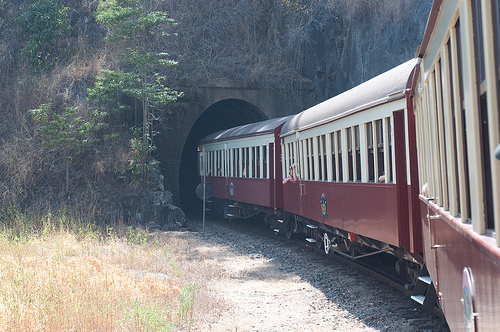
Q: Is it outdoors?
A: Yes, it is outdoors.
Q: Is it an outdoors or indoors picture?
A: It is outdoors.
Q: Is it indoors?
A: No, it is outdoors.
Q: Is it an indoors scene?
A: No, it is outdoors.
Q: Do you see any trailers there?
A: No, there are no trailers.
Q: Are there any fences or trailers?
A: No, there are no trailers or fences.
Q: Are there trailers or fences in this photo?
A: No, there are no trailers or fences.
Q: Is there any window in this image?
A: Yes, there is a window.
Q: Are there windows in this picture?
A: Yes, there is a window.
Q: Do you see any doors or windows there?
A: Yes, there is a window.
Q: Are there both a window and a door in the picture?
A: No, there is a window but no doors.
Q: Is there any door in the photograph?
A: No, there are no doors.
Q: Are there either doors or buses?
A: No, there are no doors or buses.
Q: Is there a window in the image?
A: Yes, there is a window.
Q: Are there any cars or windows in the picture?
A: Yes, there is a window.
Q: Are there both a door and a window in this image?
A: No, there is a window but no doors.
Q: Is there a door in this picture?
A: No, there are no doors.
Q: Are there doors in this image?
A: No, there are no doors.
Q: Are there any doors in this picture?
A: No, there are no doors.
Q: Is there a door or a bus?
A: No, there are no doors or buses.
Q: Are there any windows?
A: Yes, there is a window.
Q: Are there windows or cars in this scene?
A: Yes, there is a window.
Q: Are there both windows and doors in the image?
A: No, there is a window but no doors.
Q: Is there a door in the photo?
A: No, there are no doors.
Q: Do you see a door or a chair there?
A: No, there are no doors or chairs.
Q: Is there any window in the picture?
A: Yes, there are windows.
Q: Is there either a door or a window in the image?
A: Yes, there are windows.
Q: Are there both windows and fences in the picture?
A: No, there are windows but no fences.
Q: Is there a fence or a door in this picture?
A: No, there are no doors or fences.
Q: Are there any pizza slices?
A: No, there are no pizza slices.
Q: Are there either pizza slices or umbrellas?
A: No, there are no pizza slices or umbrellas.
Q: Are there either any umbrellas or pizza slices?
A: No, there are no pizza slices or umbrellas.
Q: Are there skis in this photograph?
A: No, there are no skis.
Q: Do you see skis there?
A: No, there are no skis.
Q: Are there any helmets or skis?
A: No, there are no skis or helmets.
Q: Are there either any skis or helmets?
A: No, there are no skis or helmets.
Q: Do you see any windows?
A: Yes, there is a window.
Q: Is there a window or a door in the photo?
A: Yes, there is a window.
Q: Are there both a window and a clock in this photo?
A: No, there is a window but no clocks.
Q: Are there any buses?
A: No, there are no buses.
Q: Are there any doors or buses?
A: No, there are no buses or doors.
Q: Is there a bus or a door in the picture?
A: No, there are no buses or doors.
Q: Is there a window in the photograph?
A: Yes, there is a window.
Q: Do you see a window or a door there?
A: Yes, there is a window.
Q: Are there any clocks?
A: No, there are no clocks.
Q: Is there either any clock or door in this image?
A: No, there are no clocks or doors.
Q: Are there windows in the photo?
A: Yes, there are windows.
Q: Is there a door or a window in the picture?
A: Yes, there are windows.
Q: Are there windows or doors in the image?
A: Yes, there are windows.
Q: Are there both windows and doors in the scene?
A: No, there are windows but no doors.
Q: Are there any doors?
A: No, there are no doors.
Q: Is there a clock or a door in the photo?
A: No, there are no doors or clocks.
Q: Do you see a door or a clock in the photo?
A: No, there are no doors or clocks.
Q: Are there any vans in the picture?
A: No, there are no vans.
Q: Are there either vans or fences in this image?
A: No, there are no vans or fences.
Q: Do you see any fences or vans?
A: No, there are no vans or fences.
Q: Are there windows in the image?
A: Yes, there are windows.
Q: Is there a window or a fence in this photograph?
A: Yes, there are windows.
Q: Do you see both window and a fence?
A: No, there are windows but no fences.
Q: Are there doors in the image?
A: No, there are no doors.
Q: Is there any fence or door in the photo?
A: No, there are no doors or fences.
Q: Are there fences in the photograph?
A: No, there are no fences.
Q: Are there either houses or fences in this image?
A: No, there are no fences or houses.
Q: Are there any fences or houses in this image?
A: No, there are no fences or houses.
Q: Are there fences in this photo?
A: No, there are no fences.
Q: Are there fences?
A: No, there are no fences.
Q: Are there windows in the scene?
A: Yes, there are windows.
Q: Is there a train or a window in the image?
A: Yes, there are windows.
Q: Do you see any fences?
A: No, there are no fences.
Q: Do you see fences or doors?
A: No, there are no fences or doors.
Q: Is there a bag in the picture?
A: No, there are no bags.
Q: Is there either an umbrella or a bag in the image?
A: No, there are no bags or umbrellas.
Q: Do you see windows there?
A: Yes, there are windows.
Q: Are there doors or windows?
A: Yes, there are windows.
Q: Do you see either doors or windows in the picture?
A: Yes, there are windows.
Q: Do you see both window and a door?
A: No, there are windows but no doors.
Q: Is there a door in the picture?
A: No, there are no doors.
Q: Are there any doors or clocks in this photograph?
A: No, there are no doors or clocks.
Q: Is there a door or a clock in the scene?
A: No, there are no doors or clocks.